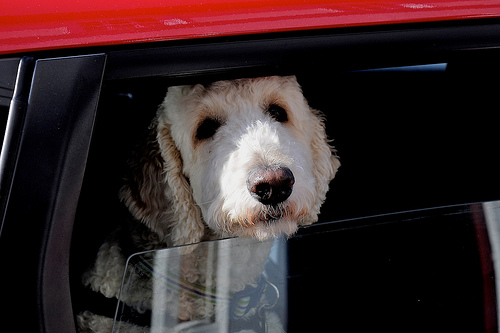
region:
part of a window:
[386, 234, 407, 257]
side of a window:
[285, 276, 300, 290]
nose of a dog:
[252, 138, 279, 193]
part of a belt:
[168, 200, 182, 227]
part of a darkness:
[387, 110, 404, 130]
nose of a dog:
[265, 175, 280, 199]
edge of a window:
[384, 233, 396, 260]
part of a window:
[386, 252, 398, 270]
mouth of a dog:
[241, 193, 263, 231]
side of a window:
[348, 264, 360, 284]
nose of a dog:
[271, 156, 292, 204]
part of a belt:
[136, 209, 151, 256]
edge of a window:
[334, 215, 339, 245]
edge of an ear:
[173, 162, 178, 177]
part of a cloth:
[130, 183, 147, 225]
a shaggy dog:
[133, 82, 353, 299]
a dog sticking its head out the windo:
[141, 75, 366, 315]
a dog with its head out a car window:
[71, 61, 347, 326]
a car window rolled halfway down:
[105, 196, 496, 326]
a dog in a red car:
[0, 0, 490, 325]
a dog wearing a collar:
[85, 75, 320, 321]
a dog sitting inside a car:
[83, 58, 380, 327]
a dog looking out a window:
[107, 35, 379, 322]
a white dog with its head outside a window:
[123, 80, 409, 332]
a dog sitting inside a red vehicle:
[142, 54, 366, 328]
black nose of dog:
[249, 172, 297, 204]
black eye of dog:
[185, 118, 235, 140]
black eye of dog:
[265, 99, 293, 123]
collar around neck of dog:
[120, 240, 275, 316]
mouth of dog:
[250, 212, 292, 227]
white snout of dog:
[198, 115, 308, 193]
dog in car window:
[55, 73, 494, 328]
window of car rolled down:
[92, 208, 497, 329]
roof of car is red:
[3, 5, 498, 52]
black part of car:
[20, 23, 497, 68]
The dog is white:
[110, 77, 350, 311]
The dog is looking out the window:
[114, 62, 328, 317]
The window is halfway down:
[98, 190, 490, 327]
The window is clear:
[101, 201, 493, 325]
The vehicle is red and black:
[6, 8, 486, 98]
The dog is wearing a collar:
[96, 227, 309, 316]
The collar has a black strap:
[226, 277, 274, 317]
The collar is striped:
[118, 238, 291, 323]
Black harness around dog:
[89, 277, 281, 327]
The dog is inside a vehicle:
[49, 45, 427, 330]